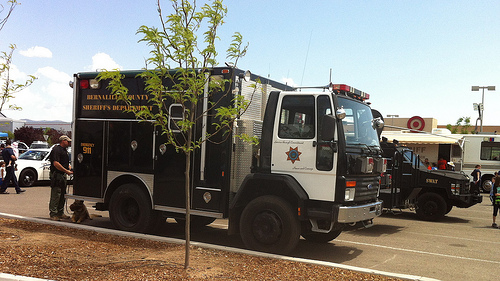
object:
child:
[6, 142, 19, 171]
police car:
[0, 148, 71, 187]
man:
[50, 135, 74, 221]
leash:
[66, 174, 73, 215]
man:
[438, 158, 448, 170]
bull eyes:
[407, 116, 425, 133]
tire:
[173, 213, 217, 228]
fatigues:
[49, 145, 69, 217]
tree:
[95, 0, 261, 274]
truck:
[380, 136, 482, 220]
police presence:
[471, 164, 481, 195]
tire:
[414, 192, 447, 221]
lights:
[346, 181, 356, 187]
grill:
[355, 177, 379, 202]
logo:
[407, 116, 425, 133]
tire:
[19, 168, 38, 185]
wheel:
[299, 220, 341, 243]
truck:
[64, 67, 384, 255]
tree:
[0, 0, 36, 113]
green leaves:
[103, 1, 265, 147]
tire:
[239, 195, 301, 255]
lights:
[332, 83, 369, 100]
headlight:
[344, 187, 355, 201]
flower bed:
[0, 211, 441, 281]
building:
[376, 114, 465, 171]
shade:
[63, 209, 112, 223]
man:
[0, 140, 27, 194]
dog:
[70, 199, 91, 223]